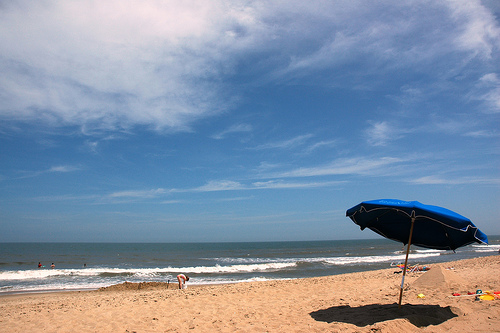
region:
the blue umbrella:
[335, 157, 493, 312]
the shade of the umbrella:
[305, 290, 468, 330]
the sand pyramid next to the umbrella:
[407, 260, 473, 300]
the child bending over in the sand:
[170, 261, 203, 304]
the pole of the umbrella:
[395, 217, 420, 318]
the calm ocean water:
[0, 236, 498, 289]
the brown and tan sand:
[3, 250, 498, 328]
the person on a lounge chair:
[381, 255, 436, 276]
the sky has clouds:
[3, 2, 494, 232]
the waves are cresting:
[2, 251, 498, 289]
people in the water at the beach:
[31, 248, 95, 272]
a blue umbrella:
[341, 190, 486, 250]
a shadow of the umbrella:
[311, 302, 455, 328]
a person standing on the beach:
[170, 269, 210, 297]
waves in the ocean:
[17, 261, 324, 271]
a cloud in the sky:
[6, 6, 283, 123]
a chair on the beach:
[400, 260, 425, 273]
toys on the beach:
[448, 287, 498, 307]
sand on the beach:
[31, 268, 484, 326]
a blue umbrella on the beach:
[346, 198, 486, 303]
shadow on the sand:
[309, 300, 456, 325]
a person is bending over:
[176, 273, 190, 289]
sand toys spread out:
[451, 287, 499, 300]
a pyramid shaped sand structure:
[414, 265, 466, 285]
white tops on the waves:
[3, 247, 438, 282]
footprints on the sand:
[183, 318, 240, 331]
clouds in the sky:
[0, 0, 498, 190]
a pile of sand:
[98, 278, 188, 290]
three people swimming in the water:
[33, 260, 90, 268]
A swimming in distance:
[48, 260, 56, 269]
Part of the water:
[90, 245, 125, 252]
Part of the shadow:
[348, 308, 384, 316]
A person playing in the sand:
[174, 270, 191, 292]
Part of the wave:
[237, 263, 257, 269]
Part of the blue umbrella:
[440, 209, 455, 218]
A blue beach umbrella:
[346, 190, 493, 317]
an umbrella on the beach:
[286, 130, 497, 270]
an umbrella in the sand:
[257, 141, 478, 289]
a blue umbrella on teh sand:
[311, 145, 479, 315]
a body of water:
[75, 230, 283, 326]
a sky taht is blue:
[34, 45, 474, 271]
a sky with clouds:
[83, 26, 398, 217]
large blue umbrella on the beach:
[345, 198, 490, 308]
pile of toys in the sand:
[448, 283, 497, 305]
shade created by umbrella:
[309, 295, 462, 330]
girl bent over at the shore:
[173, 270, 190, 292]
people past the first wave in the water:
[10, 253, 95, 271]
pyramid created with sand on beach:
[411, 261, 473, 288]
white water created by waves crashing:
[4, 262, 300, 273]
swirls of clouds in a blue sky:
[2, 3, 499, 203]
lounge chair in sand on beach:
[392, 260, 429, 274]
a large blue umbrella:
[348, 200, 487, 304]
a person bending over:
[176, 270, 191, 289]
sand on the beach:
[25, 288, 444, 330]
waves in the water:
[14, 268, 83, 283]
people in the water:
[32, 258, 105, 267]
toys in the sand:
[403, 278, 497, 307]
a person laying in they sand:
[383, 259, 438, 275]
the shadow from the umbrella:
[312, 298, 461, 329]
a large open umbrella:
[343, 192, 482, 308]